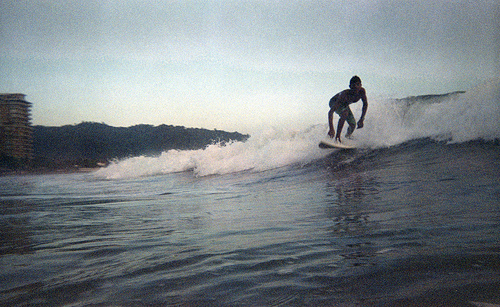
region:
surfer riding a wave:
[308, 69, 379, 177]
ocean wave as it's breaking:
[96, 114, 317, 191]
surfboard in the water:
[319, 135, 366, 152]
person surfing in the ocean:
[313, 70, 375, 159]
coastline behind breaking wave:
[41, 118, 253, 189]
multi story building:
[0, 82, 35, 181]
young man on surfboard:
[315, 68, 373, 160]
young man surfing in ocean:
[316, 70, 373, 160]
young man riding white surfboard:
[316, 71, 373, 161]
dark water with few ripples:
[126, 181, 484, 300]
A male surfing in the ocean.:
[324, 74, 369, 144]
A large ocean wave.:
[80, 73, 499, 183]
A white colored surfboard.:
[318, 129, 360, 153]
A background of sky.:
[0, 0, 499, 134]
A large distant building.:
[0, 90, 33, 171]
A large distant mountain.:
[25, 116, 247, 165]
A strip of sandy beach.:
[0, 162, 105, 174]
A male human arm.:
[354, 87, 369, 129]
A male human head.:
[347, 73, 364, 97]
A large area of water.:
[0, 83, 499, 305]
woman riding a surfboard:
[304, 63, 373, 165]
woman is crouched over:
[320, 64, 377, 143]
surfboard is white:
[316, 133, 364, 155]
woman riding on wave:
[116, 86, 498, 179]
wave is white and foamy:
[95, 80, 499, 176]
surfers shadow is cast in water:
[322, 158, 379, 273]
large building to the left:
[1, 87, 42, 172]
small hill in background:
[28, 113, 246, 185]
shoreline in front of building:
[0, 165, 101, 177]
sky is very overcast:
[1, 1, 499, 137]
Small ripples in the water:
[28, 251, 71, 301]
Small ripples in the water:
[81, 242, 146, 305]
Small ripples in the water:
[90, 234, 187, 302]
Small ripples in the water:
[175, 235, 235, 305]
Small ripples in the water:
[233, 234, 285, 305]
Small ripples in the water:
[283, 230, 322, 305]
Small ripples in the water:
[325, 222, 365, 304]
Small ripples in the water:
[353, 222, 381, 305]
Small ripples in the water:
[375, 228, 410, 305]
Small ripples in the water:
[421, 217, 496, 290]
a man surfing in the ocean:
[305, 53, 402, 165]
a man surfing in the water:
[283, 41, 433, 228]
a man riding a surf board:
[301, 36, 418, 185]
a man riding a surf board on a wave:
[230, 72, 480, 204]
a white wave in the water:
[387, 81, 494, 171]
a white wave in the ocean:
[154, 111, 316, 191]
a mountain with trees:
[40, 110, 230, 185]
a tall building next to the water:
[0, 57, 35, 184]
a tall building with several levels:
[0, 67, 40, 180]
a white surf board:
[298, 128, 364, 178]